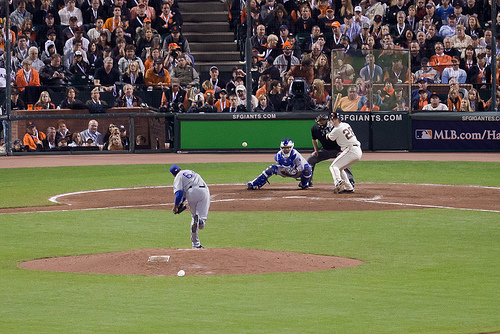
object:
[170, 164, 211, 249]
pitcher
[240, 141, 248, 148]
ball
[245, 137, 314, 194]
catcher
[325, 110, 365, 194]
batter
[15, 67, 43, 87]
jacket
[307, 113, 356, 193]
umpire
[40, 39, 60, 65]
fan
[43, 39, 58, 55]
hat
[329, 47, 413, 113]
fence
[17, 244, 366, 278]
mound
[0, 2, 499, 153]
bleacher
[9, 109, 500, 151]
wall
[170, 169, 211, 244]
uniform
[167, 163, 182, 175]
cap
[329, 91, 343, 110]
bat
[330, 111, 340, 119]
lid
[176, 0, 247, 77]
stairs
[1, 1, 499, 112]
stadium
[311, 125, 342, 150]
shirt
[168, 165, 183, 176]
head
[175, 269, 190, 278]
bag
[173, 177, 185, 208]
arm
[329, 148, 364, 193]
stance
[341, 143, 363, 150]
belt